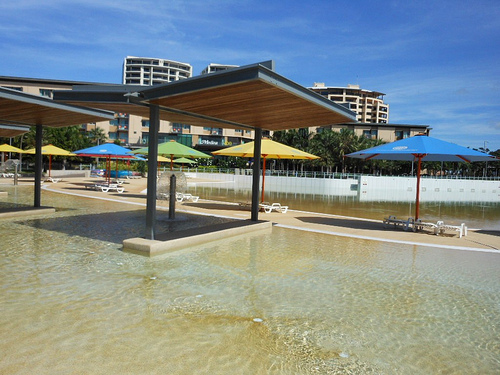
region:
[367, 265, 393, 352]
There is water that is visible here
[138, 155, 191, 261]
There is a black post that is visible here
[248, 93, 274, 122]
There is wood that is visible ehre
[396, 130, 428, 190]
There is a blue umbrella that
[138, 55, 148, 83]
There is a concrete building here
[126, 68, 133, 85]
There are bright windows visible here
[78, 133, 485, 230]
two blue umbrellas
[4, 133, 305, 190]
four yellow umbrellas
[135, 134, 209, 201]
two green umbrellas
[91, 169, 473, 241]
white benches underneath the umbrellas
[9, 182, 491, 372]
ripples on the water's surface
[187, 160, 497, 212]
white wall behind the umbrellas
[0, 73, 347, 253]
shelters in the water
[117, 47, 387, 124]
hotels in the background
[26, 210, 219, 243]
shadow of the shelter on the water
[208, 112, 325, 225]
open yellow umbrella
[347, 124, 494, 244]
open blue colored umbrella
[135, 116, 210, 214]
green colored open umbrella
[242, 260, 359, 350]
ripples in the water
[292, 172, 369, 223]
reflection in the water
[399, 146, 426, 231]
wooden support pole for an umbrella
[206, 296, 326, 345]
sunlight relected in the water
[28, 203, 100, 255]
shadow reflected on the water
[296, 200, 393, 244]
shadow from the umbrella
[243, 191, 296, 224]
beach chair by the water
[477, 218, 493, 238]
part of a board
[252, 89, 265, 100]
part of a board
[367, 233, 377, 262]
edge of a sea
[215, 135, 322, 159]
Yellow umbrella top on beach.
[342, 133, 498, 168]
Blue umbrella top on beach.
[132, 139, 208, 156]
Green umbrella top on beach.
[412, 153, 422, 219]
Pole of umbrella.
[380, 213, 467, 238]
Beach chair under umbrella.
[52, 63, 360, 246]
Pavilion providing shade.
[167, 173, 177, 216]
Small pole shooting out water.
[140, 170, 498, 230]
Water of the beach.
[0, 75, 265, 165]
Hotel next to the beach.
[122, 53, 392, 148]
Resorts behind the hotel.